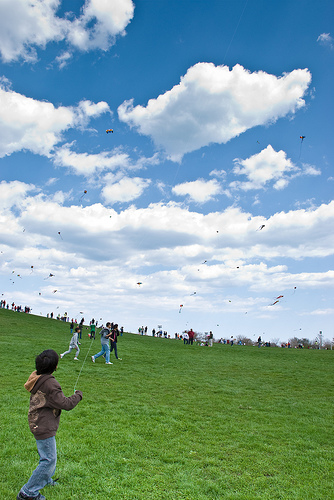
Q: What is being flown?
A: Kites.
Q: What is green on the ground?
A: Grass.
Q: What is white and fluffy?
A: Clouds.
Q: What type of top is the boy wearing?
A: Sweatshirt.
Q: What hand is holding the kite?
A: Right.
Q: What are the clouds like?
A: Fluffy.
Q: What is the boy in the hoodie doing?
A: Flying kite.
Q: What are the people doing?
A: Flying kites.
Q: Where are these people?
A: Field.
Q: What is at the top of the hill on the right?
A: Trees.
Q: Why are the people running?
A: Chasing kites.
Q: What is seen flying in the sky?
A: Kites.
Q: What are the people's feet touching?
A: Ground.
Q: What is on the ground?
A: Grass.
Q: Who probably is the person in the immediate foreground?
A: Boy.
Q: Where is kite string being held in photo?
A: Right hand.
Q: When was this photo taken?
A: Daytime.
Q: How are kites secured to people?
A: By string.